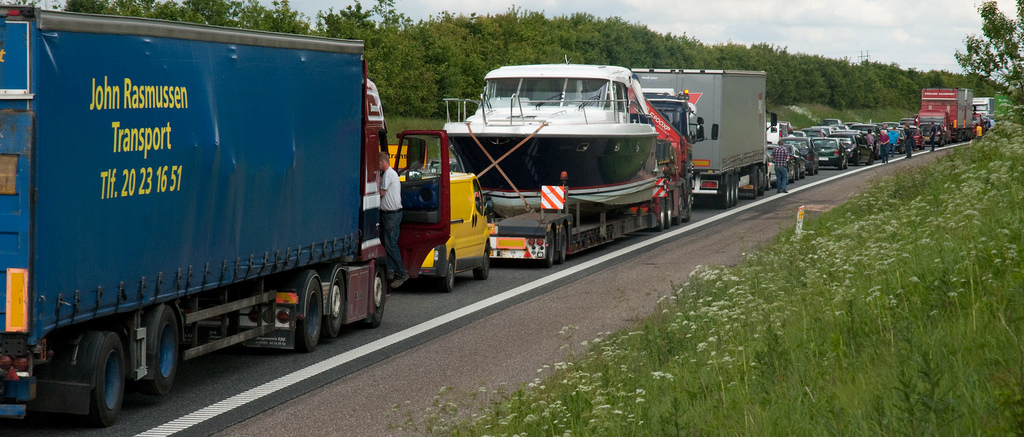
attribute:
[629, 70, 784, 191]
truck — gray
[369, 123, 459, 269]
door — open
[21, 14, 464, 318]
truck — blue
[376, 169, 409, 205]
shirt — white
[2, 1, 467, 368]
truck — blue